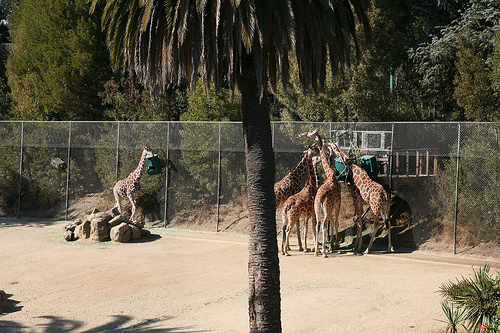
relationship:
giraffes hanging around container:
[281, 134, 399, 256] [332, 156, 351, 180]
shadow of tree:
[0, 308, 212, 333] [68, 0, 461, 333]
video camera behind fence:
[46, 156, 66, 166] [13, 110, 482, 247]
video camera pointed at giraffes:
[46, 156, 66, 166] [265, 130, 415, 253]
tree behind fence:
[68, 0, 461, 333] [4, 113, 482, 260]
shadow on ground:
[11, 300, 193, 331] [11, 224, 471, 331]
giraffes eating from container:
[281, 134, 399, 256] [327, 151, 379, 181]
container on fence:
[327, 151, 379, 181] [4, 113, 482, 260]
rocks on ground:
[58, 202, 169, 269] [0, 204, 490, 329]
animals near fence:
[112, 143, 160, 223] [7, 106, 472, 288]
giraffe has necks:
[249, 109, 445, 305] [272, 137, 389, 182]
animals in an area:
[39, 109, 414, 269] [1, 96, 471, 330]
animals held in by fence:
[112, 143, 160, 223] [11, 92, 498, 250]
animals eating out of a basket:
[112, 143, 160, 223] [144, 153, 162, 175]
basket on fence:
[139, 139, 171, 199] [15, 82, 498, 267]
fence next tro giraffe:
[4, 113, 482, 260] [63, 126, 182, 277]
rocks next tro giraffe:
[61, 205, 159, 262] [83, 136, 169, 254]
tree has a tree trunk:
[78, 2, 436, 326] [240, 53, 286, 333]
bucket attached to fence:
[332, 133, 392, 184] [1, 65, 498, 273]